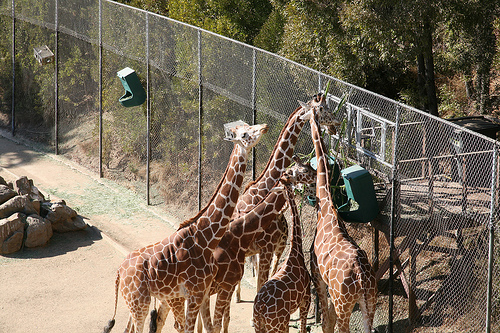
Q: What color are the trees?
A: Green.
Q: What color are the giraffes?
A: Orange and white.